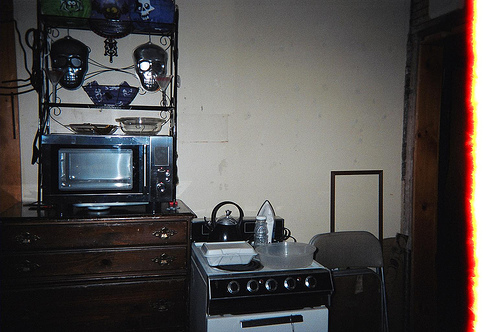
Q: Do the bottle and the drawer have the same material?
A: No, the bottle is made of plastic and the drawer is made of wood.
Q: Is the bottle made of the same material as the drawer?
A: No, the bottle is made of plastic and the drawer is made of wood.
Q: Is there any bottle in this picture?
A: Yes, there is a bottle.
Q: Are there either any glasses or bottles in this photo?
A: Yes, there is a bottle.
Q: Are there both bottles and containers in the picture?
A: Yes, there are both a bottle and a container.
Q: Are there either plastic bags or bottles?
A: Yes, there is a plastic bottle.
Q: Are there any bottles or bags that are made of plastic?
A: Yes, the bottle is made of plastic.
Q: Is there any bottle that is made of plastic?
A: Yes, there is a bottle that is made of plastic.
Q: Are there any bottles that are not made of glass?
A: Yes, there is a bottle that is made of plastic.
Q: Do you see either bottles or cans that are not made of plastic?
A: No, there is a bottle but it is made of plastic.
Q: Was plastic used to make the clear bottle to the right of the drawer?
A: Yes, the bottle is made of plastic.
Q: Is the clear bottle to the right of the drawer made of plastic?
A: Yes, the bottle is made of plastic.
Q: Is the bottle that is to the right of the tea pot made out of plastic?
A: Yes, the bottle is made of plastic.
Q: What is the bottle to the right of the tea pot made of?
A: The bottle is made of plastic.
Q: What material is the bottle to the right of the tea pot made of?
A: The bottle is made of plastic.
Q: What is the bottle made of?
A: The bottle is made of plastic.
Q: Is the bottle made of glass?
A: No, the bottle is made of plastic.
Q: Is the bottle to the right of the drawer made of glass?
A: No, the bottle is made of plastic.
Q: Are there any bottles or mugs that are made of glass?
A: No, there is a bottle but it is made of plastic.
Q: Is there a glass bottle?
A: No, there is a bottle but it is made of plastic.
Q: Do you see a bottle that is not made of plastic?
A: No, there is a bottle but it is made of plastic.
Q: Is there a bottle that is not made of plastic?
A: No, there is a bottle but it is made of plastic.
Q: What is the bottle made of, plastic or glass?
A: The bottle is made of plastic.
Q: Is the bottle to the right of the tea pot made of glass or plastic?
A: The bottle is made of plastic.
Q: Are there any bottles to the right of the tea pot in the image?
A: Yes, there is a bottle to the right of the tea pot.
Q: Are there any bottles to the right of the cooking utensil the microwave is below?
A: Yes, there is a bottle to the right of the tea pot.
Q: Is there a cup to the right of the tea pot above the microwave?
A: No, there is a bottle to the right of the tea pot.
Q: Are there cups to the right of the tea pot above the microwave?
A: No, there is a bottle to the right of the tea pot.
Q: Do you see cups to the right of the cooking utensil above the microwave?
A: No, there is a bottle to the right of the tea pot.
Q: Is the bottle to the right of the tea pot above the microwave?
A: Yes, the bottle is to the right of the tea pot.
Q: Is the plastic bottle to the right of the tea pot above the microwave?
A: Yes, the bottle is to the right of the tea pot.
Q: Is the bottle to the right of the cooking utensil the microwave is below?
A: Yes, the bottle is to the right of the tea pot.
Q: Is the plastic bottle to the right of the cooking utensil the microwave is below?
A: Yes, the bottle is to the right of the tea pot.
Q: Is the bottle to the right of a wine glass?
A: No, the bottle is to the right of the tea pot.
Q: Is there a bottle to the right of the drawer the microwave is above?
A: Yes, there is a bottle to the right of the drawer.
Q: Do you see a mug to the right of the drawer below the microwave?
A: No, there is a bottle to the right of the drawer.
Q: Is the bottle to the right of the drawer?
A: Yes, the bottle is to the right of the drawer.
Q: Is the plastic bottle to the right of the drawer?
A: Yes, the bottle is to the right of the drawer.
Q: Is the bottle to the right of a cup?
A: No, the bottle is to the right of the drawer.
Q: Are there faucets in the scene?
A: No, there are no faucets.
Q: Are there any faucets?
A: No, there are no faucets.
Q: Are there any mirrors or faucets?
A: No, there are no faucets or mirrors.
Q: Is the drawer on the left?
A: Yes, the drawer is on the left of the image.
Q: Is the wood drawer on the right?
A: No, the drawer is on the left of the image.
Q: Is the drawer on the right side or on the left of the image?
A: The drawer is on the left of the image.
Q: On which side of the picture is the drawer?
A: The drawer is on the left of the image.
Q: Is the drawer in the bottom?
A: Yes, the drawer is in the bottom of the image.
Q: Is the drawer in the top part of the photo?
A: No, the drawer is in the bottom of the image.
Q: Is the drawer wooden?
A: Yes, the drawer is wooden.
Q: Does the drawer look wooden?
A: Yes, the drawer is wooden.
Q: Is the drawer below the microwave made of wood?
A: Yes, the drawer is made of wood.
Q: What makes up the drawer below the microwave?
A: The drawer is made of wood.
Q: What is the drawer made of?
A: The drawer is made of wood.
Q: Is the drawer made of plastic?
A: No, the drawer is made of wood.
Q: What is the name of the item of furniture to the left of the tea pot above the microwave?
A: The piece of furniture is a drawer.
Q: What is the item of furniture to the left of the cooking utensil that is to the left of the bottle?
A: The piece of furniture is a drawer.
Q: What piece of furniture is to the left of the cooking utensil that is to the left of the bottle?
A: The piece of furniture is a drawer.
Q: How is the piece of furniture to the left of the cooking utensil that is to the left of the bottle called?
A: The piece of furniture is a drawer.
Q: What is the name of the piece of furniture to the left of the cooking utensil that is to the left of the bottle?
A: The piece of furniture is a drawer.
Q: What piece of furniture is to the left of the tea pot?
A: The piece of furniture is a drawer.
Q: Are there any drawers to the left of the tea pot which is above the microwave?
A: Yes, there is a drawer to the left of the tea pot.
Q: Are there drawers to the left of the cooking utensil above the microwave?
A: Yes, there is a drawer to the left of the tea pot.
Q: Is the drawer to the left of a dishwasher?
A: No, the drawer is to the left of a tea pot.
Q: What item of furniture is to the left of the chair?
A: The piece of furniture is a drawer.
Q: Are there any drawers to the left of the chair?
A: Yes, there is a drawer to the left of the chair.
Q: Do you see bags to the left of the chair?
A: No, there is a drawer to the left of the chair.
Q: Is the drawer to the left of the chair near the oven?
A: Yes, the drawer is to the left of the chair.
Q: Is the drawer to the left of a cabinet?
A: No, the drawer is to the left of the chair.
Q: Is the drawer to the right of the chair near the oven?
A: No, the drawer is to the left of the chair.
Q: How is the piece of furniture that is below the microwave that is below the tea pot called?
A: The piece of furniture is a drawer.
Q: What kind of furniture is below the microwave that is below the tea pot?
A: The piece of furniture is a drawer.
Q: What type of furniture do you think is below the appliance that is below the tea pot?
A: The piece of furniture is a drawer.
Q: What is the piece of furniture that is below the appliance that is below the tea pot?
A: The piece of furniture is a drawer.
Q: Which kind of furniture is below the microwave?
A: The piece of furniture is a drawer.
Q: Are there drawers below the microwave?
A: Yes, there is a drawer below the microwave.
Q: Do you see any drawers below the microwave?
A: Yes, there is a drawer below the microwave.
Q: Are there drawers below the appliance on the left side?
A: Yes, there is a drawer below the microwave.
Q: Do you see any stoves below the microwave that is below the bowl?
A: No, there is a drawer below the microwave.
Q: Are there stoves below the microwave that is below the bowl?
A: No, there is a drawer below the microwave.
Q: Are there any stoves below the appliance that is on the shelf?
A: No, there is a drawer below the microwave.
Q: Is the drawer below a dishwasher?
A: No, the drawer is below a microwave.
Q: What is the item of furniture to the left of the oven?
A: The piece of furniture is a drawer.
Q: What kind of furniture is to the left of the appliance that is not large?
A: The piece of furniture is a drawer.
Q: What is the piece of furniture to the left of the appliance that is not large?
A: The piece of furniture is a drawer.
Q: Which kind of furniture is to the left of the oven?
A: The piece of furniture is a drawer.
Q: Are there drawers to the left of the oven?
A: Yes, there is a drawer to the left of the oven.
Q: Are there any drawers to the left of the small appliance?
A: Yes, there is a drawer to the left of the oven.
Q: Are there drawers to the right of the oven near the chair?
A: No, the drawer is to the left of the oven.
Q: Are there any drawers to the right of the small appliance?
A: No, the drawer is to the left of the oven.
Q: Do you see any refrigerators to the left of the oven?
A: No, there is a drawer to the left of the oven.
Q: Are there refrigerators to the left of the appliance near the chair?
A: No, there is a drawer to the left of the oven.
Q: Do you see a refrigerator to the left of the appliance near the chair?
A: No, there is a drawer to the left of the oven.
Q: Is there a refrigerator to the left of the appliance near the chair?
A: No, there is a drawer to the left of the oven.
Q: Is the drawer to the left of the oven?
A: Yes, the drawer is to the left of the oven.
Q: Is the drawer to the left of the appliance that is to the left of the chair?
A: Yes, the drawer is to the left of the oven.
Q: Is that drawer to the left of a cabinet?
A: No, the drawer is to the left of the oven.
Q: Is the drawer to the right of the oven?
A: No, the drawer is to the left of the oven.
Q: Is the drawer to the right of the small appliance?
A: No, the drawer is to the left of the oven.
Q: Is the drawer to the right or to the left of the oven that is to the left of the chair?
A: The drawer is to the left of the oven.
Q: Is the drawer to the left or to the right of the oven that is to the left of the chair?
A: The drawer is to the left of the oven.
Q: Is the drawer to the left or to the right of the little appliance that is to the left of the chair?
A: The drawer is to the left of the oven.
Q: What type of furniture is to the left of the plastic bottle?
A: The piece of furniture is a drawer.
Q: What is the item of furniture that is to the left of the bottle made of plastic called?
A: The piece of furniture is a drawer.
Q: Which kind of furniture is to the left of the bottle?
A: The piece of furniture is a drawer.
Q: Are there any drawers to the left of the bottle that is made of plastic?
A: Yes, there is a drawer to the left of the bottle.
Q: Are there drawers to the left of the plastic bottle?
A: Yes, there is a drawer to the left of the bottle.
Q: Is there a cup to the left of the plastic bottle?
A: No, there is a drawer to the left of the bottle.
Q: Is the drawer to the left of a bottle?
A: Yes, the drawer is to the left of a bottle.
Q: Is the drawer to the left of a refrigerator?
A: No, the drawer is to the left of a bottle.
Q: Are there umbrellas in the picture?
A: No, there are no umbrellas.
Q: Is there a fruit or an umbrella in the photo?
A: No, there are no umbrellas or fruits.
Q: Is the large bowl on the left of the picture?
A: Yes, the bowl is on the left of the image.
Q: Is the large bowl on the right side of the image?
A: No, the bowl is on the left of the image.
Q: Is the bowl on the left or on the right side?
A: The bowl is on the left of the image.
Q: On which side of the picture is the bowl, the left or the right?
A: The bowl is on the left of the image.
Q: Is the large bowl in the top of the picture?
A: Yes, the bowl is in the top of the image.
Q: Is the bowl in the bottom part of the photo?
A: No, the bowl is in the top of the image.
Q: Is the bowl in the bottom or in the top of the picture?
A: The bowl is in the top of the image.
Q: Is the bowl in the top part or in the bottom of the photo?
A: The bowl is in the top of the image.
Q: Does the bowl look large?
A: Yes, the bowl is large.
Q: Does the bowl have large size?
A: Yes, the bowl is large.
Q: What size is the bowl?
A: The bowl is large.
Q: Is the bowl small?
A: No, the bowl is large.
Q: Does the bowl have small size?
A: No, the bowl is large.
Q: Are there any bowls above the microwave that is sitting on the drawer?
A: Yes, there is a bowl above the microwave.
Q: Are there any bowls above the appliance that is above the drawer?
A: Yes, there is a bowl above the microwave.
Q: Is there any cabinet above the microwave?
A: No, there is a bowl above the microwave.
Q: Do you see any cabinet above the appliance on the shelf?
A: No, there is a bowl above the microwave.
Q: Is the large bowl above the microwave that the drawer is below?
A: Yes, the bowl is above the microwave.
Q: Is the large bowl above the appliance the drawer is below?
A: Yes, the bowl is above the microwave.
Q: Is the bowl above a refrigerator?
A: No, the bowl is above the microwave.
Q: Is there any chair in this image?
A: Yes, there is a chair.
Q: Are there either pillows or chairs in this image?
A: Yes, there is a chair.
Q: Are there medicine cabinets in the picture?
A: No, there are no medicine cabinets.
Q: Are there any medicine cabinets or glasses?
A: No, there are no medicine cabinets or glasses.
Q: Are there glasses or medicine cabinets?
A: No, there are no medicine cabinets or glasses.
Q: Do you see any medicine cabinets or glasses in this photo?
A: No, there are no medicine cabinets or glasses.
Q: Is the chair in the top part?
A: No, the chair is in the bottom of the image.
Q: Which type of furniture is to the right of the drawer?
A: The piece of furniture is a chair.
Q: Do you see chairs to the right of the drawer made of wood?
A: Yes, there is a chair to the right of the drawer.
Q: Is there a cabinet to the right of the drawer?
A: No, there is a chair to the right of the drawer.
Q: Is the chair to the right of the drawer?
A: Yes, the chair is to the right of the drawer.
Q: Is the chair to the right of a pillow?
A: No, the chair is to the right of the drawer.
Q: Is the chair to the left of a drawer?
A: No, the chair is to the right of a drawer.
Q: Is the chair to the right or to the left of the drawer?
A: The chair is to the right of the drawer.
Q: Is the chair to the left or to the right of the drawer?
A: The chair is to the right of the drawer.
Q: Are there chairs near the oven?
A: Yes, there is a chair near the oven.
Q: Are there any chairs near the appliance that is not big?
A: Yes, there is a chair near the oven.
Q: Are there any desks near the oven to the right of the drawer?
A: No, there is a chair near the oven.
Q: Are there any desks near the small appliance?
A: No, there is a chair near the oven.